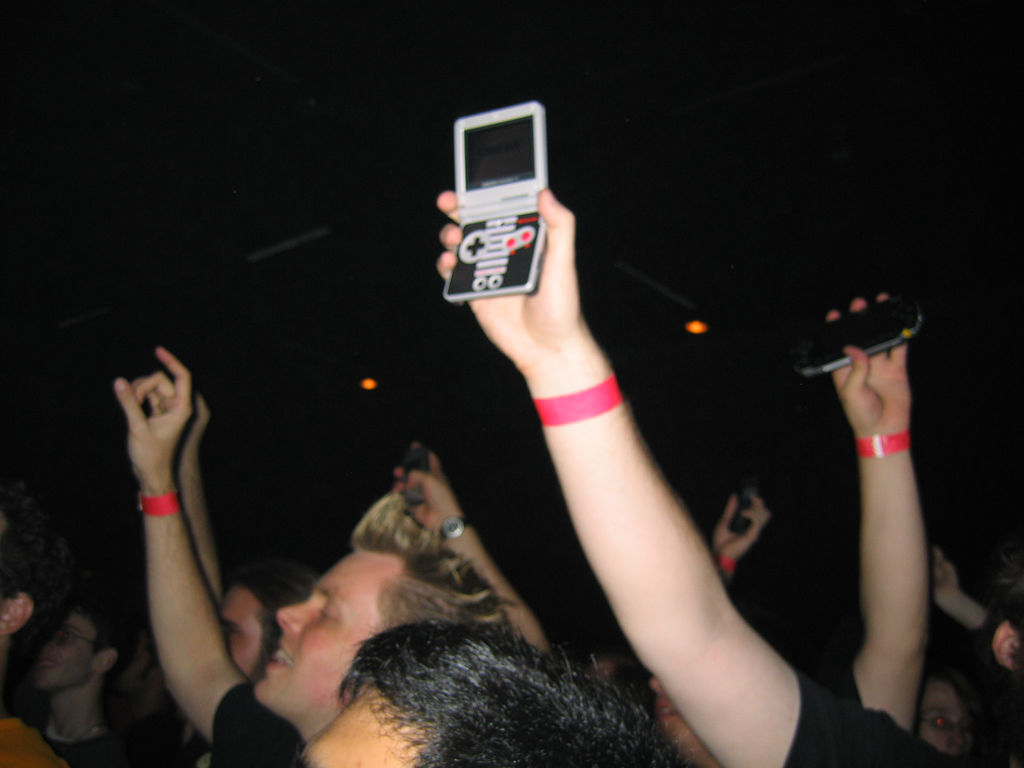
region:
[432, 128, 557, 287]
small nintendo ds in hand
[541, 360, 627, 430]
red paper wristband on wrist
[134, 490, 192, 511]
red paper wristband on wrist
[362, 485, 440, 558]
bleached blonde hair on kid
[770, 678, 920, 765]
black sleeve of t shirt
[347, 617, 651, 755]
black hair of concert goer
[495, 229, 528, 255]
red buttons on nintendo ds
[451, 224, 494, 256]
black d pad on nintendo ds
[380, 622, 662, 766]
the mans hair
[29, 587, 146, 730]
the mans head above shoulders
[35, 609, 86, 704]
the facial area of the mans head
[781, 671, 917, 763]
the mans shirt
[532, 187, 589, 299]
the mans thumb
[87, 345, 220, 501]
the mans hand at end of arm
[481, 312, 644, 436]
the mans wrist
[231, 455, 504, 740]
the mans head above shoulders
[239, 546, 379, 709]
the facial area of the mans head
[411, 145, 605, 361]
the mans hand at end of arm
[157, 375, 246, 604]
A arm in the air.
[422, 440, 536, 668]
A arm in the air.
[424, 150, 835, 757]
A arm in the air.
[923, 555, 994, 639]
A arm in the air.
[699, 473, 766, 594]
A arm in the air.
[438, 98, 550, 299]
an old color gameboy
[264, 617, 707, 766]
a person is standing up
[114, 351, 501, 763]
a person is standing up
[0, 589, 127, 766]
a person is standing up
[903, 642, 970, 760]
a person is standing up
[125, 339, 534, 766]
person is happy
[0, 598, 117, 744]
person is happy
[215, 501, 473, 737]
the head of a man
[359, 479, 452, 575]
the hair of a man